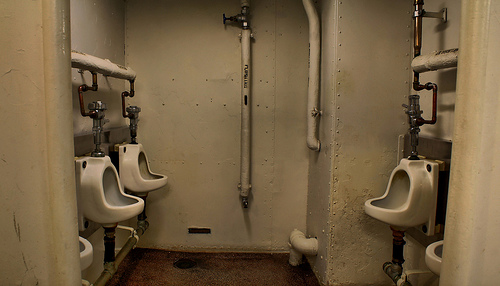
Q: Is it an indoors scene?
A: Yes, it is indoors.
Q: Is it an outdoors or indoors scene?
A: It is indoors.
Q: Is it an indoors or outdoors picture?
A: It is indoors.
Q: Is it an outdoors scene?
A: No, it is indoors.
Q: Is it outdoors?
A: No, it is indoors.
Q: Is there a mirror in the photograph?
A: No, there are no mirrors.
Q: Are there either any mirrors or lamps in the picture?
A: No, there are no mirrors or lamps.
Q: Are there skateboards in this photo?
A: No, there are no skateboards.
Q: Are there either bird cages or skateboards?
A: No, there are no skateboards or bird cages.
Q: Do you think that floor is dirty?
A: Yes, the floor is dirty.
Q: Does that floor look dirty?
A: Yes, the floor is dirty.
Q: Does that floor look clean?
A: No, the floor is dirty.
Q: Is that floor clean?
A: No, the floor is dirty.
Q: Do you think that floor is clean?
A: No, the floor is dirty.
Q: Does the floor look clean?
A: No, the floor is dirty.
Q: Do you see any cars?
A: No, there are no cars.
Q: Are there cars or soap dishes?
A: No, there are no cars or soap dishes.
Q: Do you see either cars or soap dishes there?
A: No, there are no cars or soap dishes.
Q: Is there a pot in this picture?
A: No, there are no pots.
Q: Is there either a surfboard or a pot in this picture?
A: No, there are no pots or surfboards.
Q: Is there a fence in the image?
A: No, there are no fences.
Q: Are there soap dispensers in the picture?
A: No, there are no soap dispensers.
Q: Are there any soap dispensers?
A: No, there are no soap dispensers.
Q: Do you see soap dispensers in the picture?
A: No, there are no soap dispensers.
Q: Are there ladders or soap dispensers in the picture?
A: No, there are no soap dispensers or ladders.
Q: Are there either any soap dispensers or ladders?
A: No, there are no soap dispensers or ladders.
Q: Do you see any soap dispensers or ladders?
A: No, there are no soap dispensers or ladders.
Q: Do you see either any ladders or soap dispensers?
A: No, there are no soap dispensers or ladders.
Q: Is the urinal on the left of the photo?
A: Yes, the urinal is on the left of the image.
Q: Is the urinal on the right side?
A: No, the urinal is on the left of the image.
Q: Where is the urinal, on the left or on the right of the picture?
A: The urinal is on the left of the image.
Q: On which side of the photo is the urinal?
A: The urinal is on the left of the image.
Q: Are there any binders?
A: No, there are no binders.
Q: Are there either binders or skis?
A: No, there are no binders or skis.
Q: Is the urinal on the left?
A: Yes, the urinal is on the left of the image.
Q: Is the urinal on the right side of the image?
A: No, the urinal is on the left of the image.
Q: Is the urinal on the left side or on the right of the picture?
A: The urinal is on the left of the image.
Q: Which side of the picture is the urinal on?
A: The urinal is on the left of the image.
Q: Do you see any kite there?
A: No, there are no kites.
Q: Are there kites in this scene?
A: No, there are no kites.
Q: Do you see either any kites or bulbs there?
A: No, there are no kites or bulbs.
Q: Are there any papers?
A: No, there are no papers.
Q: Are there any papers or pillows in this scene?
A: No, there are no papers or pillows.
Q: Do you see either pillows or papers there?
A: No, there are no papers or pillows.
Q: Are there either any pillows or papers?
A: No, there are no papers or pillows.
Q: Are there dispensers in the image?
A: No, there are no dispensers.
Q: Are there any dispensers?
A: No, there are no dispensers.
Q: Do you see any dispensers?
A: No, there are no dispensers.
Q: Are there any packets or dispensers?
A: No, there are no dispensers or packets.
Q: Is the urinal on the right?
A: No, the urinal is on the left of the image.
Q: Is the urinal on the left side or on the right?
A: The urinal is on the left of the image.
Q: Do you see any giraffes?
A: Yes, there is a giraffe.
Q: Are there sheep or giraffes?
A: Yes, there is a giraffe.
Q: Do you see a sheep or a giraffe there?
A: Yes, there is a giraffe.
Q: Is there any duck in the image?
A: No, there are no ducks.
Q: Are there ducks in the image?
A: No, there are no ducks.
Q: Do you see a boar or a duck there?
A: No, there are no ducks or boars.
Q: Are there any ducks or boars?
A: No, there are no ducks or boars.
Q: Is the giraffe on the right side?
A: Yes, the giraffe is on the right of the image.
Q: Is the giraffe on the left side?
A: No, the giraffe is on the right of the image.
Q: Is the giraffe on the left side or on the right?
A: The giraffe is on the right of the image.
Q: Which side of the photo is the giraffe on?
A: The giraffe is on the right of the image.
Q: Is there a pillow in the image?
A: No, there are no pillows.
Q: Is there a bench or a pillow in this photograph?
A: No, there are no pillows or benches.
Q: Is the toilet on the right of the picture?
A: Yes, the toilet is on the right of the image.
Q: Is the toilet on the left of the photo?
A: No, the toilet is on the right of the image.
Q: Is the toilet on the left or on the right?
A: The toilet is on the right of the image.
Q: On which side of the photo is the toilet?
A: The toilet is on the right of the image.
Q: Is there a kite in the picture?
A: No, there are no kites.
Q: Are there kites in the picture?
A: No, there are no kites.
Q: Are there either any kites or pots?
A: No, there are no kites or pots.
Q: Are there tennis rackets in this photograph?
A: No, there are no tennis rackets.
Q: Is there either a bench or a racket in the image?
A: No, there are no rackets or benches.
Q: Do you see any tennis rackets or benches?
A: No, there are no tennis rackets or benches.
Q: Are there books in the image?
A: No, there are no books.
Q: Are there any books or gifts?
A: No, there are no books or gifts.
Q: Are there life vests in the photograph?
A: No, there are no life vests.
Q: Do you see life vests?
A: No, there are no life vests.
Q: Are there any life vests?
A: No, there are no life vests.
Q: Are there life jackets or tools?
A: No, there are no life jackets or tools.